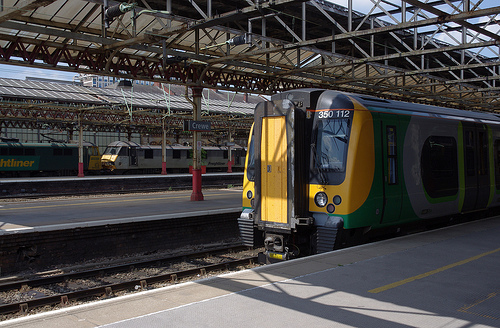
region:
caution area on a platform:
[177, 271, 282, 301]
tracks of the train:
[12, 252, 174, 299]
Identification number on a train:
[310, 100, 355, 120]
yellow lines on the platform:
[360, 250, 495, 305]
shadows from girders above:
[197, 280, 369, 310]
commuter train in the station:
[236, 70, 492, 290]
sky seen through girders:
[381, 0, 493, 47]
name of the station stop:
[177, 110, 217, 135]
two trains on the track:
[5, 125, 235, 182]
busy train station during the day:
[18, 5, 478, 290]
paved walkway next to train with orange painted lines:
[242, 258, 490, 322]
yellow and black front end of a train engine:
[230, 83, 380, 256]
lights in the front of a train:
[238, 183, 344, 217]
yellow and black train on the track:
[92, 133, 231, 174]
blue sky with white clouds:
[389, 0, 494, 53]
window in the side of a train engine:
[413, 125, 463, 204]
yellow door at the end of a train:
[252, 109, 293, 229]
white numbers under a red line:
[307, 105, 355, 119]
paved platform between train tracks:
[0, 198, 187, 227]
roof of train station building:
[0, 71, 219, 111]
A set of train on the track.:
[8, 132, 247, 178]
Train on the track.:
[226, 70, 497, 237]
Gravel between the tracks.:
[40, 234, 234, 289]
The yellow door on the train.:
[242, 94, 302, 225]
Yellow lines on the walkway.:
[358, 237, 468, 285]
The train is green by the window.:
[347, 108, 420, 236]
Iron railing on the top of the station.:
[158, 28, 472, 78]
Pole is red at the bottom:
[178, 145, 223, 203]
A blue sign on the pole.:
[182, 120, 227, 141]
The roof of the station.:
[66, 0, 318, 90]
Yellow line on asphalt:
[367, 224, 498, 297]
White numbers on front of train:
[313, 108, 351, 120]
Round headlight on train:
[312, 192, 331, 207]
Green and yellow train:
[3, 135, 106, 181]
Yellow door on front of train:
[255, 115, 289, 225]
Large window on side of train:
[425, 131, 462, 200]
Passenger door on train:
[470, 121, 491, 213]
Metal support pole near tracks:
[187, 70, 207, 202]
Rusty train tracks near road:
[3, 230, 249, 311]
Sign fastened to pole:
[183, 115, 213, 132]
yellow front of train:
[235, 81, 389, 222]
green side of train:
[341, 107, 492, 225]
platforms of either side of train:
[2, 160, 495, 327]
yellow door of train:
[255, 115, 287, 223]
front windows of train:
[243, 128, 336, 169]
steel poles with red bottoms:
[73, 93, 238, 204]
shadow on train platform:
[221, 229, 490, 327]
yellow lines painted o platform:
[315, 245, 499, 322]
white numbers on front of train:
[313, 106, 354, 123]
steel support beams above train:
[20, 4, 488, 85]